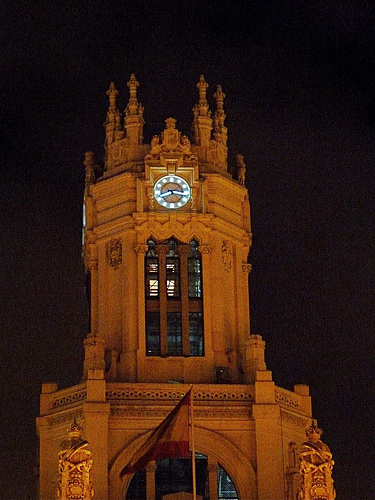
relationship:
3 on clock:
[182, 189, 188, 195] [153, 173, 192, 206]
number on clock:
[179, 196, 187, 206] [151, 173, 192, 208]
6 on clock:
[171, 198, 180, 209] [151, 170, 194, 212]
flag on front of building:
[119, 383, 206, 497] [56, 75, 338, 499]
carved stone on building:
[290, 424, 340, 497] [56, 75, 338, 499]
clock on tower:
[145, 166, 193, 210] [81, 76, 258, 337]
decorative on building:
[106, 230, 124, 278] [39, 49, 290, 346]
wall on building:
[89, 100, 290, 459] [50, 92, 354, 498]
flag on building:
[119, 383, 206, 497] [30, 68, 339, 499]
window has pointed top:
[142, 234, 163, 354] [186, 231, 205, 249]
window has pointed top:
[164, 229, 185, 349] [164, 232, 182, 243]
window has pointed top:
[185, 230, 204, 359] [142, 229, 158, 247]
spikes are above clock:
[84, 60, 261, 196] [116, 173, 210, 220]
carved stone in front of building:
[290, 424, 340, 497] [30, 68, 339, 499]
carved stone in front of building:
[57, 420, 93, 497] [30, 68, 339, 499]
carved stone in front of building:
[57, 420, 93, 497] [20, 62, 308, 392]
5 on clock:
[175, 200, 183, 208] [151, 173, 192, 208]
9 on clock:
[155, 183, 162, 194] [151, 173, 192, 208]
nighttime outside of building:
[255, 99, 342, 304] [30, 68, 339, 499]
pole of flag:
[187, 391, 202, 498] [108, 374, 221, 477]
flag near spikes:
[119, 383, 206, 497] [84, 60, 261, 196]